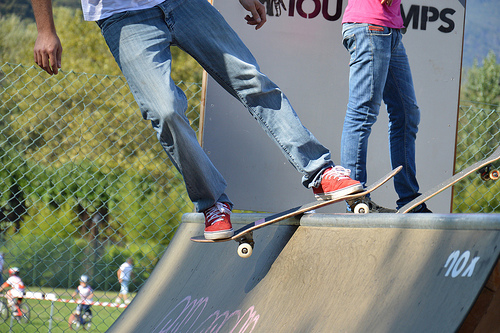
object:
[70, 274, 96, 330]
child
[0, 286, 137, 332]
grass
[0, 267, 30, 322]
child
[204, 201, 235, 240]
shoe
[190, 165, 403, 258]
skateboard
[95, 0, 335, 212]
jeans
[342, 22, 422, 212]
jeans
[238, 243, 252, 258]
wheel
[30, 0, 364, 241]
boy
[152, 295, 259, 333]
writing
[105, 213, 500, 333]
ramp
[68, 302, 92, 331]
bike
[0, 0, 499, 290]
trees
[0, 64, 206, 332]
fence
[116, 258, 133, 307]
man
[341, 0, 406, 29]
shirt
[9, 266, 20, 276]
helmet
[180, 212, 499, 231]
rail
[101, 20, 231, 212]
leg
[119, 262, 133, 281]
shirt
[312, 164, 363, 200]
shoe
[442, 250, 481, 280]
writing